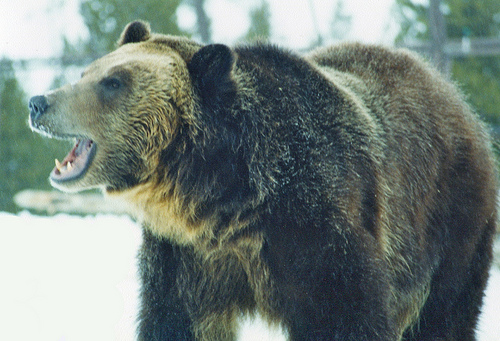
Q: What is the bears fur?
A: Brown.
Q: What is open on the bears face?
A: Mouth.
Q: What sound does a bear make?
A: Roar.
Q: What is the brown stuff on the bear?
A: Fur.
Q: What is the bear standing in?
A: Snow.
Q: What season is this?
A: Winter.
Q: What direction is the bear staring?
A: Left.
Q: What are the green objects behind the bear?
A: Trees.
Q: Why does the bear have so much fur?
A: Winter.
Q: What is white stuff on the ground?
A: Snow.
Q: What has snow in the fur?
A: The bear.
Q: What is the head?
A: Of the bear.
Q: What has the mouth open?
A: The bear.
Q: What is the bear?
A: Brown.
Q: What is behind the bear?
A: Green trees.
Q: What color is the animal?
A: Brown.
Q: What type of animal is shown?
A: Bear.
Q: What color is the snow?
A: White.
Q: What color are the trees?
A: Green.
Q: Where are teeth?
A: In bear's mouth.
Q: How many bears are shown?
A: One.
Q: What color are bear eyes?
A: Black.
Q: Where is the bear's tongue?
A: In mouth.